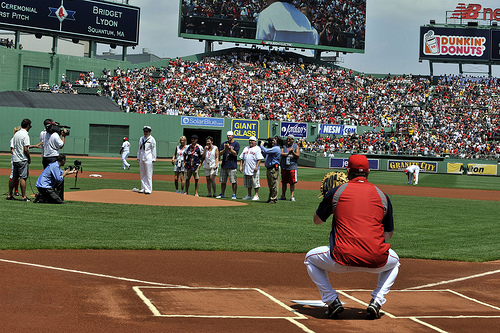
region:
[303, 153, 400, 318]
the catcher crouching down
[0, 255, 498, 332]
the white lines on the dirt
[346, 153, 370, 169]
the hat on the catcher's head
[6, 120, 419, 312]
the people on the field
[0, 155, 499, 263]
the lush green grass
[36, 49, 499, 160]
the people in the audience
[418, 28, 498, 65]
the large billboard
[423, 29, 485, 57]
the dunkin donuts logo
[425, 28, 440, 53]
the picture of the dunkin donuts cup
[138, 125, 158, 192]
the man in the white uniform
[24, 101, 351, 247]
people standing around pitcher's mound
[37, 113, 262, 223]
sailor standing on pitcher's mound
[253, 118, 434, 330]
baseball player with glove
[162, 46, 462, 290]
crowd of people at baseball stadium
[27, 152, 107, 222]
guy kneeling on grass with camera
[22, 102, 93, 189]
guy holding television camera on shoulder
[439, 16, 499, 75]
pink, orange, and white advertisement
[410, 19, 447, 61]
cup of coffee advertisement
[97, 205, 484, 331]
batter's box and home plate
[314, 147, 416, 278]
orange, black, and gray shirt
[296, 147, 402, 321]
a catcher crouching on the ground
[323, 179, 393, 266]
he is wearing a red shirt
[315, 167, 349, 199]
he is holding a yellow glove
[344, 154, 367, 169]
he is wearing a red cap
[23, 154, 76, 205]
a photographer kneeling down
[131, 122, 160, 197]
a person in a uniform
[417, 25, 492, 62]
a Dunkin Donuts advertisement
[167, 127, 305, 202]
people standing in a line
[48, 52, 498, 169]
a crowd in the stands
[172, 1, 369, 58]
a large screen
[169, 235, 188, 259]
part of a field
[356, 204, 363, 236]
back of a man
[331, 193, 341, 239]
part of a shirt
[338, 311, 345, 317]
part of a shoe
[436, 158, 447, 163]
part of a board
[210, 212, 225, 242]
edge of a field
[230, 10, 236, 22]
part of a screen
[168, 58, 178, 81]
part of the crowd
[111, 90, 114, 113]
section of a crowd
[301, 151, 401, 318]
A man squatting at home plate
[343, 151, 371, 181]
A man wearing a red cap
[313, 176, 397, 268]
A man wearing a red and black shirt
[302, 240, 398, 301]
A man wearing white pants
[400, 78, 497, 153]
A crowd of spectators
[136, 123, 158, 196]
A man in a sailor suit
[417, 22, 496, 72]
A billboard advertising Dunkin' Donuts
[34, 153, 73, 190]
A man wearing a blue shirt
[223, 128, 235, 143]
A man wearing a white cap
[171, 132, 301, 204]
A group of people